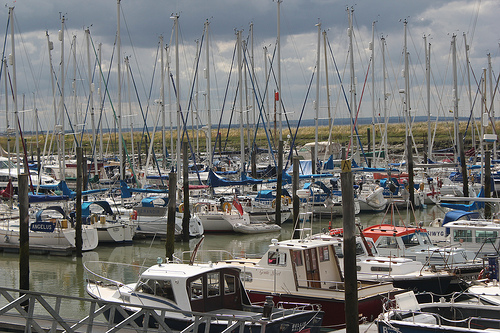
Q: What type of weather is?
A: It is cloudy.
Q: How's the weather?
A: It is cloudy.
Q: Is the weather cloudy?
A: Yes, it is cloudy.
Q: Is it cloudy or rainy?
A: It is cloudy.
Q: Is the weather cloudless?
A: No, it is cloudy.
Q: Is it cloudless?
A: No, it is cloudy.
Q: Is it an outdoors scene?
A: Yes, it is outdoors.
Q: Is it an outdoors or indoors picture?
A: It is outdoors.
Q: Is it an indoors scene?
A: No, it is outdoors.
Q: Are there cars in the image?
A: No, there are no cars.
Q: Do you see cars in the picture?
A: No, there are no cars.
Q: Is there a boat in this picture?
A: Yes, there is a boat.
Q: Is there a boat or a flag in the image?
A: Yes, there is a boat.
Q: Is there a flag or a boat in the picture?
A: Yes, there is a boat.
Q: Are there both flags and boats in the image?
A: Yes, there are both a boat and a flag.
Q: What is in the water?
A: The boat is in the water.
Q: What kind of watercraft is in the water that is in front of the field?
A: The watercraft is a boat.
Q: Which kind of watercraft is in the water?
A: The watercraft is a boat.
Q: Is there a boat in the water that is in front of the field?
A: Yes, there is a boat in the water.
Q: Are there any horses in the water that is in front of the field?
A: No, there is a boat in the water.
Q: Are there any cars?
A: No, there are no cars.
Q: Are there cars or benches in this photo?
A: No, there are no cars or benches.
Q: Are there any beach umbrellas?
A: No, there are no beach umbrellas.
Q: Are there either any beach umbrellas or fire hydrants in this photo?
A: No, there are no beach umbrellas or fire hydrants.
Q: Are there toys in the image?
A: No, there are no toys.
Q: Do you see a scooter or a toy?
A: No, there are no toys or scooters.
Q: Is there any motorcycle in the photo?
A: No, there are no motorcycles.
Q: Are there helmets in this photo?
A: No, there are no helmets.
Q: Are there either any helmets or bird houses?
A: No, there are no helmets or bird houses.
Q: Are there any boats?
A: Yes, there is a boat.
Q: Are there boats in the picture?
A: Yes, there is a boat.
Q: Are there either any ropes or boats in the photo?
A: Yes, there is a boat.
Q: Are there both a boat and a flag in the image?
A: Yes, there are both a boat and a flag.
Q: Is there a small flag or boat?
A: Yes, there is a small boat.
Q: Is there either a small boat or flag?
A: Yes, there is a small boat.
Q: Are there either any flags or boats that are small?
A: Yes, the boat is small.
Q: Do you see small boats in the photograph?
A: Yes, there is a small boat.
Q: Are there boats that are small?
A: Yes, there is a boat that is small.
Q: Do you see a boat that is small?
A: Yes, there is a boat that is small.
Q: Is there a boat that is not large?
A: Yes, there is a small boat.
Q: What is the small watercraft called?
A: The watercraft is a boat.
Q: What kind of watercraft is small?
A: The watercraft is a boat.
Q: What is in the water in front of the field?
A: The boat is in the water.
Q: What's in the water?
A: The boat is in the water.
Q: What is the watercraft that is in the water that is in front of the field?
A: The watercraft is a boat.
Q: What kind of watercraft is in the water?
A: The watercraft is a boat.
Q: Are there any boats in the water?
A: Yes, there is a boat in the water.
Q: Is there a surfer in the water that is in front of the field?
A: No, there is a boat in the water.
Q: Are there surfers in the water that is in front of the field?
A: No, there is a boat in the water.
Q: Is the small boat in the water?
A: Yes, the boat is in the water.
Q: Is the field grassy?
A: Yes, the field is grassy.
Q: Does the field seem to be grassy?
A: Yes, the field is grassy.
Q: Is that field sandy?
A: No, the field is grassy.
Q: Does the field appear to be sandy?
A: No, the field is grassy.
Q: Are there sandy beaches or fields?
A: No, there is a field but it is grassy.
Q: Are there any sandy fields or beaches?
A: No, there is a field but it is grassy.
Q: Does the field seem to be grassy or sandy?
A: The field is grassy.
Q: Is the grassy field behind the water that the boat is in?
A: Yes, the field is behind the water.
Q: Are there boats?
A: Yes, there is a boat.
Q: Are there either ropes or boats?
A: Yes, there is a boat.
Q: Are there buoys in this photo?
A: No, there are no buoys.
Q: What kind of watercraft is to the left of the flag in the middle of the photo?
A: The watercraft is a boat.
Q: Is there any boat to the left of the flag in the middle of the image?
A: Yes, there is a boat to the left of the flag.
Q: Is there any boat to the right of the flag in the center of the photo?
A: No, the boat is to the left of the flag.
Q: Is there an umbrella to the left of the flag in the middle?
A: No, there is a boat to the left of the flag.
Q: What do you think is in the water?
A: The boat is in the water.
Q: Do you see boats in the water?
A: Yes, there is a boat in the water.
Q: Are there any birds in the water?
A: No, there is a boat in the water.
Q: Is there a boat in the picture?
A: Yes, there is a boat.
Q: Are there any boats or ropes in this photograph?
A: Yes, there is a boat.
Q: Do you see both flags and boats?
A: Yes, there are both a boat and a flag.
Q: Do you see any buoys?
A: No, there are no buoys.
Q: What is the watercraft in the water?
A: The watercraft is a boat.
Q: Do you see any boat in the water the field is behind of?
A: Yes, there is a boat in the water.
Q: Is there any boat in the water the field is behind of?
A: Yes, there is a boat in the water.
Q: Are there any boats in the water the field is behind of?
A: Yes, there is a boat in the water.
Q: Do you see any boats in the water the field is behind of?
A: Yes, there is a boat in the water.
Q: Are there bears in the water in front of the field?
A: No, there is a boat in the water.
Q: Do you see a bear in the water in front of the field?
A: No, there is a boat in the water.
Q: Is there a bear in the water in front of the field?
A: No, there is a boat in the water.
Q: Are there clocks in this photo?
A: No, there are no clocks.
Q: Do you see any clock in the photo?
A: No, there are no clocks.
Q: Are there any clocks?
A: No, there are no clocks.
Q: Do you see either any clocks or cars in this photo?
A: No, there are no clocks or cars.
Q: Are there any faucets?
A: No, there are no faucets.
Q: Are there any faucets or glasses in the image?
A: No, there are no faucets or glasses.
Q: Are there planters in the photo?
A: No, there are no planters.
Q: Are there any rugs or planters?
A: No, there are no planters or rugs.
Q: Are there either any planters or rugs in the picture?
A: No, there are no planters or rugs.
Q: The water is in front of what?
A: The water is in front of the field.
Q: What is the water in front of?
A: The water is in front of the field.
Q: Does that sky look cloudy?
A: Yes, the sky is cloudy.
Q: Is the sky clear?
A: No, the sky is cloudy.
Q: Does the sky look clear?
A: No, the sky is cloudy.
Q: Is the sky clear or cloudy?
A: The sky is cloudy.